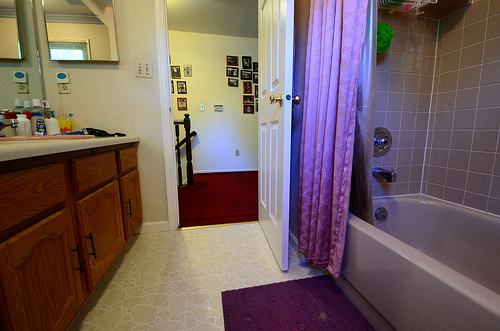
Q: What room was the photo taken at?
A: It was taken at the bathroom.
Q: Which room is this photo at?
A: It is at the bathroom.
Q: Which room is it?
A: It is a bathroom.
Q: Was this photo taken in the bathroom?
A: Yes, it was taken in the bathroom.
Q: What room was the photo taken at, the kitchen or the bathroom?
A: It was taken at the bathroom.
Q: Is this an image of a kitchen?
A: No, the picture is showing a bathroom.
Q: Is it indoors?
A: Yes, it is indoors.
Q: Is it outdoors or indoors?
A: It is indoors.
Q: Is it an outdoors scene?
A: No, it is indoors.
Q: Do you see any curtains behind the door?
A: Yes, there is a curtain behind the door.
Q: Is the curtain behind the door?
A: Yes, the curtain is behind the door.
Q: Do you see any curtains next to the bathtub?
A: Yes, there is a curtain next to the bathtub.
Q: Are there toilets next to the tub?
A: No, there is a curtain next to the tub.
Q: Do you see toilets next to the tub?
A: No, there is a curtain next to the tub.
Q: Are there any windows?
A: Yes, there is a window.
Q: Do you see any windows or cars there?
A: Yes, there is a window.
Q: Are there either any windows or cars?
A: Yes, there is a window.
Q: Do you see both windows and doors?
A: Yes, there are both a window and a door.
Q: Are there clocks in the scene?
A: No, there are no clocks.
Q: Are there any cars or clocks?
A: No, there are no clocks or cars.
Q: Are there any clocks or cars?
A: No, there are no clocks or cars.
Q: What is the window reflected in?
A: The window is reflected in the mirror.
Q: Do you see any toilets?
A: No, there are no toilets.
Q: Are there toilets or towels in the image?
A: No, there are no toilets or towels.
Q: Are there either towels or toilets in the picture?
A: No, there are no toilets or towels.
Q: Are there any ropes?
A: No, there are no ropes.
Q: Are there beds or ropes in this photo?
A: No, there are no ropes or beds.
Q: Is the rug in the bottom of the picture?
A: Yes, the rug is in the bottom of the image.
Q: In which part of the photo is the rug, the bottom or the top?
A: The rug is in the bottom of the image.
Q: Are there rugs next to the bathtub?
A: Yes, there is a rug next to the bathtub.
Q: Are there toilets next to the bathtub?
A: No, there is a rug next to the bathtub.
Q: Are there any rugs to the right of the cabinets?
A: Yes, there is a rug to the right of the cabinets.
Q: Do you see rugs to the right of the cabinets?
A: Yes, there is a rug to the right of the cabinets.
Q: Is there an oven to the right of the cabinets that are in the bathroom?
A: No, there is a rug to the right of the cabinets.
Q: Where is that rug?
A: The rug is on the floor.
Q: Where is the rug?
A: The rug is on the floor.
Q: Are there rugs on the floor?
A: Yes, there is a rug on the floor.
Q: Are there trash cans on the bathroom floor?
A: No, there is a rug on the floor.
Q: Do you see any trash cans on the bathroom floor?
A: No, there is a rug on the floor.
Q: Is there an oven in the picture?
A: No, there are no ovens.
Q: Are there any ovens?
A: No, there are no ovens.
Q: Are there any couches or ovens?
A: No, there are no ovens or couches.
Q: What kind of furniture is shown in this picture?
A: The furniture is cabinets.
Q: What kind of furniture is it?
A: The pieces of furniture are cabinets.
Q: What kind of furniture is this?
A: These are cabinets.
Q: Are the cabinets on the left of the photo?
A: Yes, the cabinets are on the left of the image.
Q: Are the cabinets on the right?
A: No, the cabinets are on the left of the image.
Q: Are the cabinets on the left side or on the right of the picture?
A: The cabinets are on the left of the image.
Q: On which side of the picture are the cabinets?
A: The cabinets are on the left of the image.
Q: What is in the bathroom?
A: The cabinets are in the bathroom.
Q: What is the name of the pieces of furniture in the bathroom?
A: The pieces of furniture are cabinets.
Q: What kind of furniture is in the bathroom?
A: The pieces of furniture are cabinets.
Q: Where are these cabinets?
A: The cabinets are in the bathroom.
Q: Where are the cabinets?
A: The cabinets are in the bathroom.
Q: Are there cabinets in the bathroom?
A: Yes, there are cabinets in the bathroom.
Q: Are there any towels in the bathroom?
A: No, there are cabinets in the bathroom.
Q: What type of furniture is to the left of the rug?
A: The pieces of furniture are cabinets.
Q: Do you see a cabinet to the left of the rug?
A: Yes, there are cabinets to the left of the rug.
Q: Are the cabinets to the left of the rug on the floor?
A: Yes, the cabinets are to the left of the rug.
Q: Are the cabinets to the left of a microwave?
A: No, the cabinets are to the left of the rug.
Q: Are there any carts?
A: No, there are no carts.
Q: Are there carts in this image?
A: No, there are no carts.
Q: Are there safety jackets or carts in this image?
A: No, there are no carts or safety jackets.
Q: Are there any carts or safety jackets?
A: No, there are no carts or safety jackets.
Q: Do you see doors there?
A: Yes, there is a door.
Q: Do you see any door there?
A: Yes, there is a door.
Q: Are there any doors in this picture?
A: Yes, there is a door.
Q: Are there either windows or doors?
A: Yes, there is a door.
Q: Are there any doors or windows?
A: Yes, there is a door.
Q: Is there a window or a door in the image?
A: Yes, there is a door.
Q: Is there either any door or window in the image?
A: Yes, there is a door.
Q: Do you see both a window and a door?
A: Yes, there are both a door and a window.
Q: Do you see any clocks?
A: No, there are no clocks.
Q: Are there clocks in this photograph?
A: No, there are no clocks.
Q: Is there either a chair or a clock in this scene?
A: No, there are no clocks or chairs.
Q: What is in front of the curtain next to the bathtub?
A: The door is in front of the curtain.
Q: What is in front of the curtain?
A: The door is in front of the curtain.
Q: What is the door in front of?
A: The door is in front of the curtain.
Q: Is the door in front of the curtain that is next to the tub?
A: Yes, the door is in front of the curtain.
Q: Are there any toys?
A: No, there are no toys.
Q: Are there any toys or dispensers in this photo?
A: No, there are no toys or dispensers.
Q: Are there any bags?
A: No, there are no bags.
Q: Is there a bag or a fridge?
A: No, there are no bags or refrigerators.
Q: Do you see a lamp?
A: No, there are no lamps.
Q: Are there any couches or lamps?
A: No, there are no lamps or couches.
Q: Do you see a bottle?
A: Yes, there is a bottle.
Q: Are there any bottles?
A: Yes, there is a bottle.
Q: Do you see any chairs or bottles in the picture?
A: Yes, there is a bottle.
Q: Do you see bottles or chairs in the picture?
A: Yes, there is a bottle.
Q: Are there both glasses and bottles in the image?
A: No, there is a bottle but no glasses.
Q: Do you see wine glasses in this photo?
A: No, there are no wine glasses.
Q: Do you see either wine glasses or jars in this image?
A: No, there are no wine glasses or jars.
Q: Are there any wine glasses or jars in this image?
A: No, there are no wine glasses or jars.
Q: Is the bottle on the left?
A: Yes, the bottle is on the left of the image.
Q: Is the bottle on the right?
A: No, the bottle is on the left of the image.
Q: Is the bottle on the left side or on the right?
A: The bottle is on the left of the image.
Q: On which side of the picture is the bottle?
A: The bottle is on the left of the image.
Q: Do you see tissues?
A: No, there are no tissues.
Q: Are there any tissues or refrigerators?
A: No, there are no tissues or refrigerators.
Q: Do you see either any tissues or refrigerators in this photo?
A: No, there are no tissues or refrigerators.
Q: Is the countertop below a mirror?
A: Yes, the countertop is below a mirror.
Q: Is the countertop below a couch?
A: No, the countertop is below a mirror.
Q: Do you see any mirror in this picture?
A: Yes, there is a mirror.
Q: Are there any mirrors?
A: Yes, there is a mirror.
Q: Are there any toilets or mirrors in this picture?
A: Yes, there is a mirror.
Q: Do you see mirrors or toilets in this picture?
A: Yes, there is a mirror.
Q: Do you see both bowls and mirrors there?
A: No, there is a mirror but no bowls.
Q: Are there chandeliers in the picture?
A: No, there are no chandeliers.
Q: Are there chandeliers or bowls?
A: No, there are no chandeliers or bowls.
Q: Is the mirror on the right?
A: No, the mirror is on the left of the image.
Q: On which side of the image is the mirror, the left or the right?
A: The mirror is on the left of the image.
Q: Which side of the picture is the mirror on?
A: The mirror is on the left of the image.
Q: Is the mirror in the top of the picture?
A: Yes, the mirror is in the top of the image.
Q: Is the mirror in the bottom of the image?
A: No, the mirror is in the top of the image.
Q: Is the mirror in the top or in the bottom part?
A: The mirror is in the top of the image.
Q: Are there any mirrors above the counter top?
A: Yes, there is a mirror above the counter top.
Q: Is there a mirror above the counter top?
A: Yes, there is a mirror above the counter top.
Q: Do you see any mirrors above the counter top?
A: Yes, there is a mirror above the counter top.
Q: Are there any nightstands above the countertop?
A: No, there is a mirror above the countertop.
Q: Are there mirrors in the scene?
A: Yes, there is a mirror.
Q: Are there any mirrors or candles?
A: Yes, there is a mirror.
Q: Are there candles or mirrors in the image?
A: Yes, there is a mirror.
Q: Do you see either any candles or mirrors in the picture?
A: Yes, there is a mirror.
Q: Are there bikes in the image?
A: No, there are no bikes.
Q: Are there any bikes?
A: No, there are no bikes.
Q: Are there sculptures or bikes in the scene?
A: No, there are no bikes or sculptures.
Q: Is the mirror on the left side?
A: Yes, the mirror is on the left of the image.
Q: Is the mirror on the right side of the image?
A: No, the mirror is on the left of the image.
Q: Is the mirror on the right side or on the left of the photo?
A: The mirror is on the left of the image.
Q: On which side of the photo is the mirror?
A: The mirror is on the left of the image.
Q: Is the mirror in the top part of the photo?
A: Yes, the mirror is in the top of the image.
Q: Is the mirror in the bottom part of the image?
A: No, the mirror is in the top of the image.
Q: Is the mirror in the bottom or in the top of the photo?
A: The mirror is in the top of the image.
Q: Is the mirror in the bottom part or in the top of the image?
A: The mirror is in the top of the image.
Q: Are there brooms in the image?
A: No, there are no brooms.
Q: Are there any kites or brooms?
A: No, there are no brooms or kites.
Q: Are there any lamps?
A: No, there are no lamps.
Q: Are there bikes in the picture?
A: No, there are no bikes.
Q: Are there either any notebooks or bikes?
A: No, there are no bikes or notebooks.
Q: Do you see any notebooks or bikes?
A: No, there are no bikes or notebooks.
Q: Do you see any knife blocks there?
A: No, there are no knife blocks.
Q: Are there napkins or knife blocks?
A: No, there are no knife blocks or napkins.